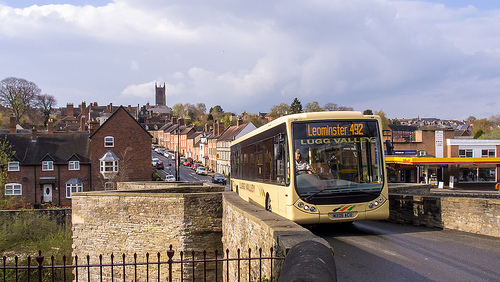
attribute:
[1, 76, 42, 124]
tree — bare, leafless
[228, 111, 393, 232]
bus — white, large, numbered, electic, pale, blue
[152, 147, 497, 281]
road — paved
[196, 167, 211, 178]
car — lined, parked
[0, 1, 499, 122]
sky — blue, overcast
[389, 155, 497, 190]
station — red, yellow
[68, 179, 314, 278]
bridge — stone, small, middle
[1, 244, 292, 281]
fence — iron, black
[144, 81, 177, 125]
church — tower, old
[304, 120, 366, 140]
placard — yellow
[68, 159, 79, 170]
window — bay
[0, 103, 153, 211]
building — brick